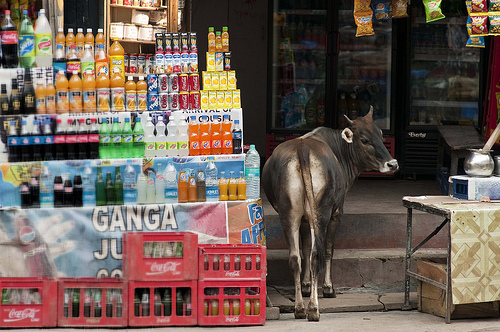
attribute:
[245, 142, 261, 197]
bottle — of water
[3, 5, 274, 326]
beverages — different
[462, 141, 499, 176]
pot — metal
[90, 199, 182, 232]
lettering — white 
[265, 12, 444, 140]
refrigerator — beverage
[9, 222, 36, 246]
logo — pepsi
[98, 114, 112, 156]
soda — assorted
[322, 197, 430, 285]
stairs — red, grey 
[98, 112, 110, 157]
soda — lemon, lime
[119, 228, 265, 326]
bins — red, soda, plastic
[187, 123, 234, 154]
liquid — orange